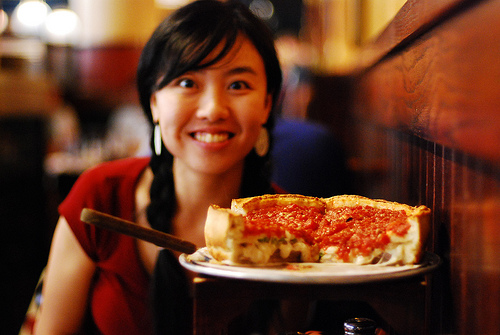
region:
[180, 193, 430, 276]
a deep pan pizza on a white plate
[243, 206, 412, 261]
tomato sauce on top of the deep pan pizza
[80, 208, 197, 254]
a wooden handle to a utensil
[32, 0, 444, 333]
a woman sitting in a booth inside a restaurant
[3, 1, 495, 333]
a woman in a red short sleeve blouse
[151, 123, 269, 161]
a pair of earings in the woman's ears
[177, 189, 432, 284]
a deep pan pizza with tomato sauce on the top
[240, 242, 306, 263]
melted mozzarella cheese inside the deep pan pizza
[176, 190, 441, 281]
a partially eaten deep dish pizza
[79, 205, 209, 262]
a wooden handle slicer under the deep pan pizza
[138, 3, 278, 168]
A woman's smiling face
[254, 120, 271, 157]
A large round earring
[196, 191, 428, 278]
Some food on a white plate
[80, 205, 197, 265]
The wooden handle of a spatula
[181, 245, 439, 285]
A white dinner plate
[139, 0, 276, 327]
A girl with long black pigtails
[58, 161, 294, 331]
A red shirt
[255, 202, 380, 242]
Red sauce spilling out of the food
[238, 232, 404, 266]
A layer of white cheese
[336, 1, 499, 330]
A wood panel wall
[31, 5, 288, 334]
A woman in a red shirt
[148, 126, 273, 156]
A pair of large round earrings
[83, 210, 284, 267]
A spatula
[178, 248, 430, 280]
A white ceramic plate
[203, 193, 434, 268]
A pie on the plate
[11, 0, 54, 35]
an overhanging light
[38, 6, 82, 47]
an overhanging light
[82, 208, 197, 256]
a wooden handle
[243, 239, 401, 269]
some melted cheese on the pie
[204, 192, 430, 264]
A large thick pizza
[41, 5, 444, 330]
woman holding plate of stuffed pizza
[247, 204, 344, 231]
tomato sauce on pizza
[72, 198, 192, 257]
handle of a spatula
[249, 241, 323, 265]
cheese inside a pizza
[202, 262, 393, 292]
white plate pizza is on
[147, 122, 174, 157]
earring on woman's right ear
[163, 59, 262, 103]
eyes of a woman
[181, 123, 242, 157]
smile on a woman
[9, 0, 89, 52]
lights illuminated in the background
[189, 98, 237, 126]
nose of a woman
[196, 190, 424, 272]
the deep dish pizza on the trey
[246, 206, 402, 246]
sauce on top of the pizza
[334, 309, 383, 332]
the silver top of the shaker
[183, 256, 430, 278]
the white trey to the pizza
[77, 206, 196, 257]
the brown handle for the pizza scooper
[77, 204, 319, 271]
the scooper under the pizza slice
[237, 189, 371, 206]
the baked crust of the pizza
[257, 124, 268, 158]
a round earing on the girls ear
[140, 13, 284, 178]
the smiling women at the table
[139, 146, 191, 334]
the ponytail of the women